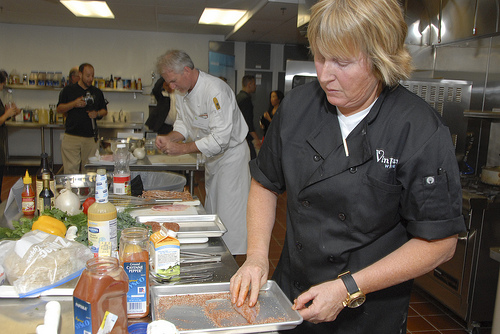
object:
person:
[228, 2, 471, 328]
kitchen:
[0, 1, 499, 334]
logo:
[375, 146, 401, 171]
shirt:
[246, 77, 466, 304]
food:
[147, 220, 179, 231]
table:
[0, 189, 278, 334]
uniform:
[172, 70, 252, 255]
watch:
[337, 272, 367, 310]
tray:
[148, 278, 304, 333]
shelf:
[0, 77, 145, 93]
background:
[0, 22, 240, 183]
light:
[61, 0, 115, 22]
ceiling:
[3, 3, 309, 44]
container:
[116, 226, 151, 317]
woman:
[260, 90, 283, 129]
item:
[28, 70, 39, 84]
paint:
[2, 25, 218, 78]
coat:
[161, 70, 249, 158]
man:
[56, 63, 109, 172]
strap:
[338, 269, 359, 295]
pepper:
[32, 215, 68, 237]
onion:
[55, 178, 81, 215]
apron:
[201, 141, 254, 256]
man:
[231, 75, 263, 161]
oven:
[420, 176, 500, 322]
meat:
[248, 312, 271, 325]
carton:
[72, 255, 130, 333]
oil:
[113, 144, 133, 197]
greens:
[0, 218, 33, 239]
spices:
[168, 297, 173, 302]